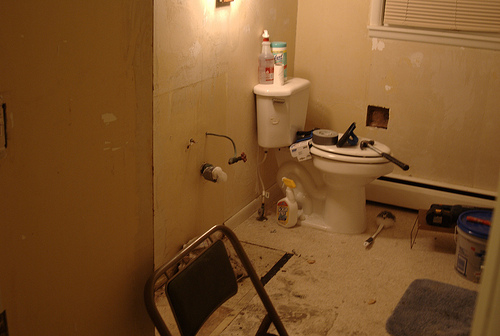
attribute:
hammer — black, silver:
[359, 138, 411, 171]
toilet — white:
[254, 69, 395, 235]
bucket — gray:
[454, 224, 488, 283]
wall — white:
[294, 0, 500, 193]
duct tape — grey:
[314, 127, 340, 146]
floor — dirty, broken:
[155, 191, 481, 335]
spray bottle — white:
[275, 174, 302, 227]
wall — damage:
[1, 1, 157, 335]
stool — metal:
[144, 223, 291, 335]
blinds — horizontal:
[384, 0, 499, 35]